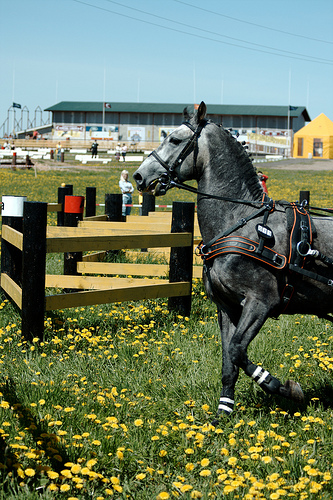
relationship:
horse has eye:
[132, 99, 320, 418] [167, 135, 179, 147]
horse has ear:
[132, 99, 320, 418] [180, 107, 192, 123]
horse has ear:
[132, 99, 320, 418] [194, 98, 209, 126]